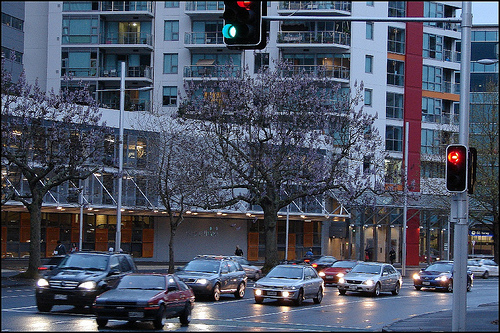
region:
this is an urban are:
[95, 68, 443, 300]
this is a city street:
[40, 17, 420, 252]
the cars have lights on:
[195, 254, 390, 331]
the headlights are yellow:
[243, 285, 355, 315]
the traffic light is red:
[420, 140, 490, 207]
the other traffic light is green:
[207, 20, 293, 57]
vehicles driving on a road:
[37, 248, 472, 326]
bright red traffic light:
[444, 148, 463, 166]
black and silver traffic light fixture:
[442, 143, 469, 193]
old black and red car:
[88, 270, 195, 328]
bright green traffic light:
[218, 20, 240, 38]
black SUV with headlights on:
[33, 245, 139, 315]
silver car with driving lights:
[252, 262, 324, 304]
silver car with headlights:
[337, 259, 404, 297]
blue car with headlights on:
[410, 257, 473, 294]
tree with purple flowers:
[0, 48, 109, 281]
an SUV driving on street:
[33, 252, 138, 312]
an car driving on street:
[94, 273, 194, 332]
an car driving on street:
[170, 257, 248, 299]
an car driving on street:
[252, 262, 324, 307]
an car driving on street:
[337, 260, 400, 297]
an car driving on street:
[410, 260, 472, 292]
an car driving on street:
[319, 258, 360, 283]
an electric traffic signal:
[446, 144, 466, 194]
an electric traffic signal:
[221, 0, 261, 48]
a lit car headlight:
[36, 277, 48, 286]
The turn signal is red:
[428, 135, 498, 237]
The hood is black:
[85, 284, 167, 312]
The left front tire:
[144, 302, 177, 328]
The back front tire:
[179, 295, 211, 330]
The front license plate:
[121, 304, 147, 321]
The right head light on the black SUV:
[72, 277, 96, 293]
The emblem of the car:
[52, 279, 73, 290]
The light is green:
[210, 20, 249, 43]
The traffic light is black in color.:
[441, 145, 469, 195]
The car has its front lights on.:
[36, 276, 96, 294]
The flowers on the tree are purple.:
[164, 66, 393, 212]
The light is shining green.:
[221, 24, 236, 40]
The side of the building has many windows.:
[361, 2, 378, 177]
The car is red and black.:
[91, 269, 195, 328]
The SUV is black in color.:
[33, 246, 138, 321]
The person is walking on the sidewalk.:
[231, 244, 243, 256]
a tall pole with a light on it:
[442, 137, 477, 331]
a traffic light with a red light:
[442, 138, 474, 330]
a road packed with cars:
[24, 220, 494, 330]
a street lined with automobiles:
[22, 227, 493, 329]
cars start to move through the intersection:
[29, 233, 477, 328]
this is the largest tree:
[169, 59, 379, 280]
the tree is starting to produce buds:
[173, 52, 369, 284]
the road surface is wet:
[0, 271, 499, 331]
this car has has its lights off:
[88, 266, 200, 331]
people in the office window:
[49, 235, 85, 260]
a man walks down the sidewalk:
[230, 241, 245, 256]